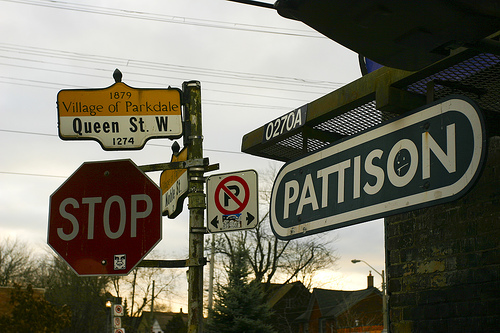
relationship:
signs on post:
[45, 66, 261, 280] [178, 77, 208, 329]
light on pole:
[331, 248, 371, 269] [361, 261, 389, 331]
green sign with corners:
[270, 95, 488, 242] [452, 148, 484, 198]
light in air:
[347, 257, 368, 265] [357, 231, 380, 254]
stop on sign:
[52, 190, 152, 239] [45, 157, 162, 278]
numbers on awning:
[261, 110, 293, 145] [242, 77, 371, 140]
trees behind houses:
[196, 235, 284, 290] [256, 266, 383, 328]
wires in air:
[1, 0, 349, 195] [155, 30, 195, 46]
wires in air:
[1, 62, 308, 102] [155, 30, 195, 46]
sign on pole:
[56, 70, 187, 156] [188, 77, 204, 331]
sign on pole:
[204, 167, 259, 231] [188, 77, 204, 331]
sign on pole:
[45, 157, 162, 278] [188, 77, 204, 331]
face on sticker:
[107, 250, 128, 270] [110, 252, 129, 270]